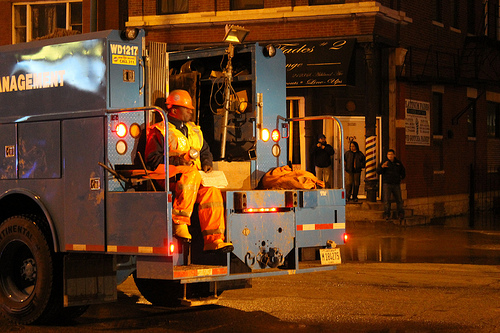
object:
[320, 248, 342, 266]
license plate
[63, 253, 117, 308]
flap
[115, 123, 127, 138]
light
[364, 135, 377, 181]
stripes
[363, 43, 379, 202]
pole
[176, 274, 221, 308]
step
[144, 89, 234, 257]
man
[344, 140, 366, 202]
man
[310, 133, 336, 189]
man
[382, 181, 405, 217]
jeans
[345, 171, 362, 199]
jeans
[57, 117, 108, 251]
compartments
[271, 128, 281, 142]
light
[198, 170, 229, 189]
papers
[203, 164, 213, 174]
hand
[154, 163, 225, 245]
pants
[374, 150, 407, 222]
man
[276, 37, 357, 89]
sign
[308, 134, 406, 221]
people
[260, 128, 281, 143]
lights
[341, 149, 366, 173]
coat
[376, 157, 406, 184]
coat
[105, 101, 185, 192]
bar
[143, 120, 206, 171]
worker/safety vest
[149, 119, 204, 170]
vest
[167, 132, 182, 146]
orange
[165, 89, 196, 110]
hardhat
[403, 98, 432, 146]
square sign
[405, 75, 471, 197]
wall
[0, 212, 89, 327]
tire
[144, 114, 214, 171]
shirt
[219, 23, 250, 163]
portable light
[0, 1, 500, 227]
building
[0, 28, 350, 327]
truck